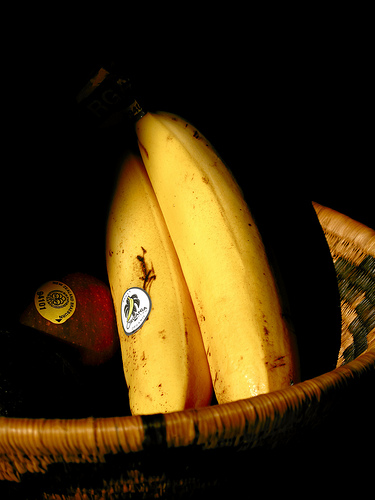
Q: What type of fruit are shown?
A: Bananas and apple.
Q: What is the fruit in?
A: Basket.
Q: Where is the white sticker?
A: Banana.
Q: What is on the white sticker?
A: Banana.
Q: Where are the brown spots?
A: Bananas.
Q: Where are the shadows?
A: Background, left side, and around the fruit.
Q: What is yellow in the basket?
A: Bananas.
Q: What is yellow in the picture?
A: A banana.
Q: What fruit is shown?
A: Bananas.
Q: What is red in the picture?
A: Apple.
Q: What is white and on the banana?
A: Sticker.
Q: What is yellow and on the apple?
A: Sticker.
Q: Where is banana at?
A: Basket.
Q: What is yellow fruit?
A: Banana.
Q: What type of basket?
A: Wicker.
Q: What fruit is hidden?
A: Apple.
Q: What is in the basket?
A: Fruit.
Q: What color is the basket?
A: Brown.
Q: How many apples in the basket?
A: One.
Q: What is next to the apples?
A: Bananas.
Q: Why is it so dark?
A: Light is off.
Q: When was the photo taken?
A: Night time.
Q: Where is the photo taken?
A: In a kitchen.